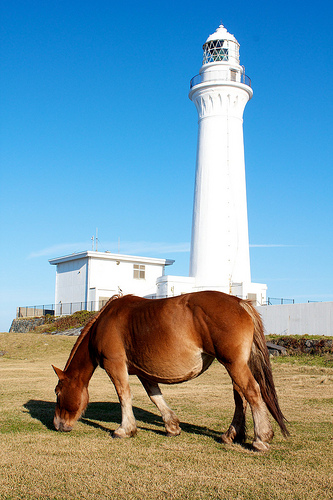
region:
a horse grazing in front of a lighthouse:
[35, 26, 294, 452]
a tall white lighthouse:
[179, 18, 278, 280]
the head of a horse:
[44, 358, 97, 438]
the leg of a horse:
[106, 371, 140, 441]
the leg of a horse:
[139, 384, 191, 441]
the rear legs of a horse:
[219, 363, 278, 456]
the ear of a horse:
[47, 362, 64, 380]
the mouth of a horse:
[56, 417, 65, 434]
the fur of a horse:
[125, 309, 206, 359]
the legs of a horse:
[110, 383, 278, 453]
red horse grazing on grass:
[14, 292, 302, 464]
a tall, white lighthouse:
[189, 16, 257, 291]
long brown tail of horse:
[244, 308, 297, 440]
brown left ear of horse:
[51, 364, 62, 379]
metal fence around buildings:
[16, 295, 306, 322]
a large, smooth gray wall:
[248, 297, 328, 331]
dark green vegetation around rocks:
[276, 334, 323, 365]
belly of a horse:
[137, 344, 205, 382]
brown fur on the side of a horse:
[124, 307, 195, 352]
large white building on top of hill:
[47, 250, 174, 331]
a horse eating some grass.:
[46, 287, 290, 454]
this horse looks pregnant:
[27, 280, 299, 483]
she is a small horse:
[38, 285, 292, 459]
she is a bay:
[36, 262, 302, 455]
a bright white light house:
[191, 14, 276, 297]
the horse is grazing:
[34, 294, 294, 451]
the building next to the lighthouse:
[45, 236, 181, 304]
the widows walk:
[177, 61, 263, 109]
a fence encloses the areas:
[257, 301, 330, 339]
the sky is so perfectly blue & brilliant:
[70, 39, 175, 137]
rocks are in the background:
[269, 332, 330, 366]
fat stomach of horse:
[125, 343, 201, 381]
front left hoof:
[110, 418, 141, 437]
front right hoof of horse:
[158, 418, 186, 436]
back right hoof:
[217, 421, 242, 441]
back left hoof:
[245, 414, 277, 449]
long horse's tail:
[239, 299, 295, 437]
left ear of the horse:
[47, 361, 64, 379]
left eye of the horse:
[52, 389, 63, 396]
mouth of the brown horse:
[52, 422, 74, 431]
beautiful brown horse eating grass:
[45, 291, 292, 453]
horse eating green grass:
[32, 300, 290, 455]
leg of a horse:
[102, 359, 145, 439]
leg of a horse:
[139, 377, 187, 432]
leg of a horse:
[234, 362, 272, 450]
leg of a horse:
[220, 383, 256, 441]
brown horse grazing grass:
[44, 277, 310, 450]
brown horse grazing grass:
[29, 279, 299, 452]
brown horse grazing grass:
[44, 279, 299, 457]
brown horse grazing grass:
[40, 285, 303, 458]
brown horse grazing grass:
[42, 286, 298, 462]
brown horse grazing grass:
[38, 287, 295, 463]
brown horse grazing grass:
[24, 285, 303, 454]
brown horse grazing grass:
[44, 284, 303, 458]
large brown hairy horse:
[49, 294, 291, 452]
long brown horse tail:
[239, 300, 293, 439]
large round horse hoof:
[115, 425, 140, 441]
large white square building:
[47, 250, 176, 319]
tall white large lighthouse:
[188, 22, 253, 283]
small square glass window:
[132, 261, 145, 277]